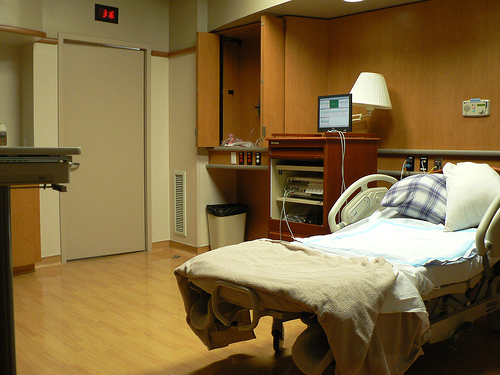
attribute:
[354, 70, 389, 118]
lamp — tilted, white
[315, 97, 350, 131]
monitor — small, computer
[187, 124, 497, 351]
bed — hospital style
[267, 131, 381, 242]
dresser — brown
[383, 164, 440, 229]
pillow — plaid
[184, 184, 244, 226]
bag — black, trash bag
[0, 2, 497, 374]
room — facility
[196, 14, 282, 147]
cabinet — open, tan, wooden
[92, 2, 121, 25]
clock — digital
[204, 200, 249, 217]
bag — black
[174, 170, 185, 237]
vent — white 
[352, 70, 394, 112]
lamp shade — white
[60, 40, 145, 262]
door — tan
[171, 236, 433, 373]
blanket — folded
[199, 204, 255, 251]
trash bin — for trash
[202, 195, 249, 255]
can — gray, trash can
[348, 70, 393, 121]
lamp — on dresser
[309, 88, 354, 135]
monitor — displaying, information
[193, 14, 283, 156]
doors — open